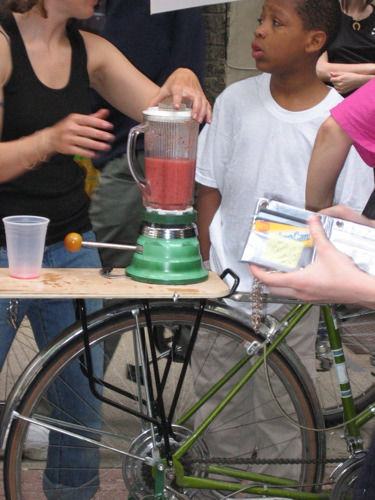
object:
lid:
[144, 100, 193, 120]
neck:
[266, 58, 319, 98]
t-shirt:
[193, 70, 373, 319]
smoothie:
[140, 155, 194, 208]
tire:
[3, 297, 330, 498]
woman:
[5, 8, 116, 175]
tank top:
[9, 49, 92, 124]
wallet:
[234, 196, 371, 294]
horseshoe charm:
[352, 20, 360, 31]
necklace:
[344, 5, 369, 31]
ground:
[196, 41, 244, 73]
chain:
[136, 442, 360, 493]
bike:
[7, 275, 373, 495]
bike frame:
[1, 284, 369, 496]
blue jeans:
[1, 228, 110, 492]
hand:
[45, 104, 118, 162]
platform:
[38, 85, 252, 215]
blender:
[121, 101, 212, 284]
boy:
[192, 0, 374, 498]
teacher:
[0, 0, 218, 496]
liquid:
[144, 156, 196, 208]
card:
[252, 218, 318, 246]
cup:
[3, 213, 51, 279]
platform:
[0, 267, 231, 301]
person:
[243, 194, 362, 320]